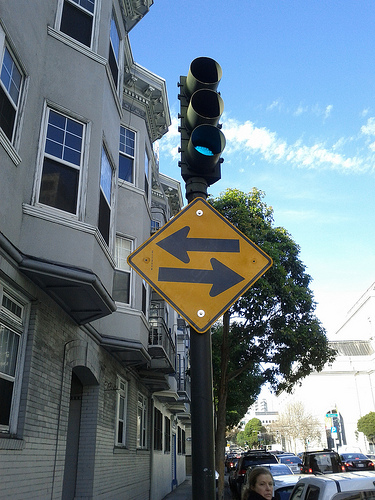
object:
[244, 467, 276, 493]
hair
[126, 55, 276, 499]
sign post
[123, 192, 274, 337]
street sign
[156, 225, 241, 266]
arrows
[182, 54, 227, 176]
traffic light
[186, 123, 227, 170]
light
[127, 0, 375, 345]
sky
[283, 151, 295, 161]
clouds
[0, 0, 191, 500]
building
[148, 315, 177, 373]
balconies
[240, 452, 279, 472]
woman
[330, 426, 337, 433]
parking sign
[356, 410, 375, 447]
tree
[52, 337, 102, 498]
archway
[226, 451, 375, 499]
street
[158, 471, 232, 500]
sidewalk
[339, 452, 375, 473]
car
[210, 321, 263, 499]
trees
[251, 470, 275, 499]
face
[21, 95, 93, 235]
windows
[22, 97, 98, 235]
window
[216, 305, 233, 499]
tree trunk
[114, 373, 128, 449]
windows